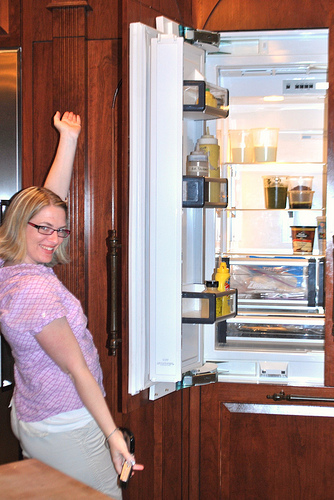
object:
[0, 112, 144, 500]
woman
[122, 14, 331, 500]
refrigerator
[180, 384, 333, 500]
door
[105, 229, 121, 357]
handle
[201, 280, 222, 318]
bottle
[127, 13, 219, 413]
door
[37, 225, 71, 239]
glasses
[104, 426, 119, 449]
bracelet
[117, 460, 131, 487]
item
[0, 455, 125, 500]
counter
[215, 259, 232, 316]
mustard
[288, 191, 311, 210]
salsa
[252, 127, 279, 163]
container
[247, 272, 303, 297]
lunch meat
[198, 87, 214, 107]
lemon juice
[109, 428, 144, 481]
right hand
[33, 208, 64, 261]
face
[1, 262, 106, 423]
blouse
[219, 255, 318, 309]
drawer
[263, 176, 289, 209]
cup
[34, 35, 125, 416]
paneling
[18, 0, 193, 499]
cabinet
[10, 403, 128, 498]
shorts